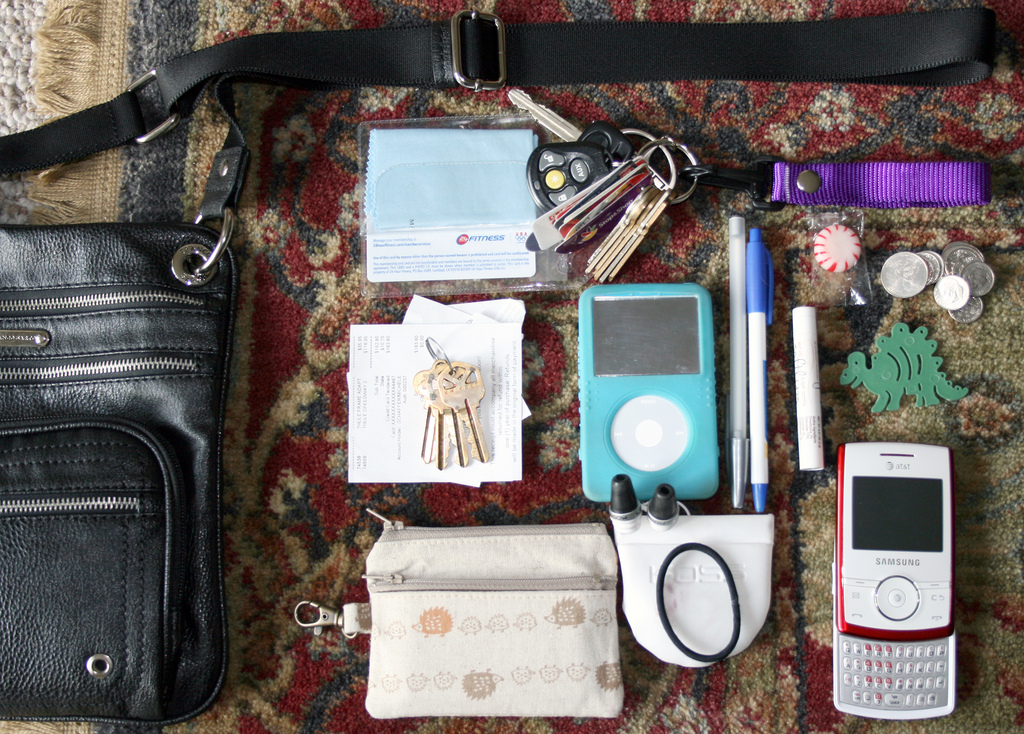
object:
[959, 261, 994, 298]
coin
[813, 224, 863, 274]
mint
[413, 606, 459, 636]
porcupine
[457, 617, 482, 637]
porcupine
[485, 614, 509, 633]
porcupine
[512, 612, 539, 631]
porcupine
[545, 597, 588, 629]
porcupine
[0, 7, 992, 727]
crossbody bag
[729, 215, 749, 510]
pen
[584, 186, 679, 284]
key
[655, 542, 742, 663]
hair tie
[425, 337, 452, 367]
keyring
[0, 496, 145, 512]
zipper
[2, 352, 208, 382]
zipper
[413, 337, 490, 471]
set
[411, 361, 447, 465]
car key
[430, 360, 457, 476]
car key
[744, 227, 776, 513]
ballpoint pen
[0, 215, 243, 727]
purse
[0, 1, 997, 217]
strap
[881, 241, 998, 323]
collection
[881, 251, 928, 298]
coin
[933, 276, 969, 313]
coin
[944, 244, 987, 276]
coin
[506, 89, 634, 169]
key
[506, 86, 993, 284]
key ring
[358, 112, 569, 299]
lanyard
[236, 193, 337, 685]
rug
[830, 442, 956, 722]
item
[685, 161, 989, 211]
item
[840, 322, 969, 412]
item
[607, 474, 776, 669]
item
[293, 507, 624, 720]
item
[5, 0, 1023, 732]
rug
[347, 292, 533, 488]
item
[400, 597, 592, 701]
design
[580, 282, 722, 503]
ipod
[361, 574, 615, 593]
zipper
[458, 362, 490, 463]
key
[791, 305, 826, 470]
chalk stick